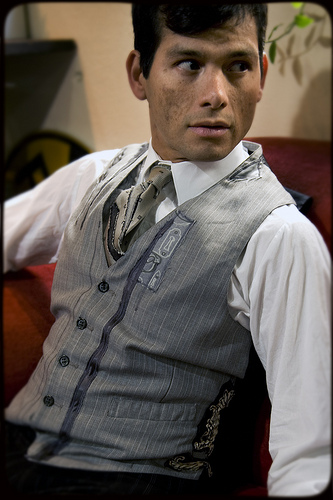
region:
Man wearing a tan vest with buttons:
[1, 0, 331, 484]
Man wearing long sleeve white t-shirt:
[5, 2, 331, 489]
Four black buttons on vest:
[31, 268, 115, 418]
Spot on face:
[154, 80, 182, 120]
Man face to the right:
[10, 3, 323, 236]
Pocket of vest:
[98, 390, 204, 439]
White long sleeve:
[226, 209, 325, 491]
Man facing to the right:
[2, 1, 325, 272]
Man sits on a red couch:
[6, 113, 330, 499]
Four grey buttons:
[36, 272, 118, 423]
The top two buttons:
[71, 268, 120, 332]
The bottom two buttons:
[37, 350, 76, 413]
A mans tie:
[110, 159, 174, 257]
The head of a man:
[84, 3, 289, 164]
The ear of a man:
[124, 44, 146, 101]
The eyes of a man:
[171, 45, 254, 81]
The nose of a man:
[194, 82, 238, 111]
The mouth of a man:
[178, 114, 236, 138]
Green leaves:
[271, 6, 319, 62]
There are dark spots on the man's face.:
[142, 93, 183, 122]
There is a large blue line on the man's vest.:
[83, 343, 110, 374]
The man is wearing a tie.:
[126, 183, 159, 199]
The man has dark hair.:
[166, 15, 204, 29]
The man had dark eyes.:
[227, 61, 260, 78]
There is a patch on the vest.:
[143, 231, 178, 253]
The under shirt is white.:
[267, 254, 295, 282]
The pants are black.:
[18, 474, 66, 490]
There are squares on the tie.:
[136, 175, 157, 202]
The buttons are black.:
[86, 278, 113, 297]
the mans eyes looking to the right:
[174, 49, 254, 78]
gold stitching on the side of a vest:
[165, 367, 238, 482]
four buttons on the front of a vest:
[37, 261, 116, 440]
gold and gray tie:
[79, 138, 167, 277]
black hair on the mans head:
[119, 3, 276, 38]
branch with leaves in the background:
[263, 3, 321, 87]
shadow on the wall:
[280, 43, 323, 92]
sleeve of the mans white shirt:
[215, 209, 331, 489]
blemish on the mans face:
[150, 75, 188, 145]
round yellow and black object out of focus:
[9, 117, 96, 185]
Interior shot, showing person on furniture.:
[13, 16, 328, 492]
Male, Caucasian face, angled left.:
[129, 9, 266, 161]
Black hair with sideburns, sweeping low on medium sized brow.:
[138, 3, 251, 73]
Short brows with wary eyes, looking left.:
[171, 46, 258, 91]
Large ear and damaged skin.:
[125, 59, 186, 135]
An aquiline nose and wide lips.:
[191, 68, 244, 150]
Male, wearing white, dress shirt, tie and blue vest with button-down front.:
[29, 44, 332, 493]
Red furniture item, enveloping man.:
[0, 118, 332, 454]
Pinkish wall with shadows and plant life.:
[270, 9, 331, 144]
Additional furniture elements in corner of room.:
[6, 12, 80, 174]